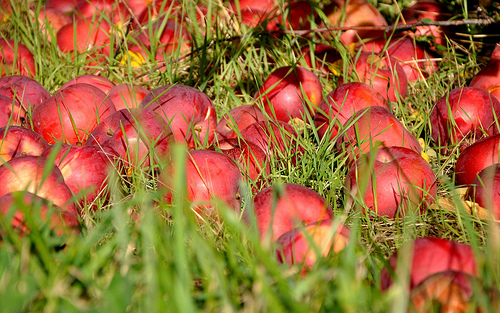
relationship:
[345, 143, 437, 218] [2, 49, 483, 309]
apple in field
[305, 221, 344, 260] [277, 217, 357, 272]
yellow spots on apple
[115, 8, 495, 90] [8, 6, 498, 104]
branch on apples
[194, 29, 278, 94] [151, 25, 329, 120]
shadow on grass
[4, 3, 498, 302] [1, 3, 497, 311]
apples strewn on ground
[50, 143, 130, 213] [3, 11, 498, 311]
apple in grass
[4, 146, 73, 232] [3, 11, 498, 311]
apple in grass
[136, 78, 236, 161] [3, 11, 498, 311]
apple in grass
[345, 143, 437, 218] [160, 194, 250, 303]
apple on floor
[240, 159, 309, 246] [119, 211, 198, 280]
apple on ground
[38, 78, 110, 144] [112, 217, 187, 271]
apple in grass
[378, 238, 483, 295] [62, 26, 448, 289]
apple in field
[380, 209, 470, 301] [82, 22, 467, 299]
apple in field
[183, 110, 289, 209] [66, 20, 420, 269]
apple in field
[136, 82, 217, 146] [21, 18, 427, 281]
apple in field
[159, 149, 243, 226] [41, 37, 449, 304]
apple in field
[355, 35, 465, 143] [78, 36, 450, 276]
apple in field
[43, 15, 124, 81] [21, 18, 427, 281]
apple in field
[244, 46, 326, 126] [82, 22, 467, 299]
apple in field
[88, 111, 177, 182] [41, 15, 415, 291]
apple in grass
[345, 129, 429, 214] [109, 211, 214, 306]
apple on grass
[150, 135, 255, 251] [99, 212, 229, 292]
apple on grass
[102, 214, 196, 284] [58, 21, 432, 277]
grass with apples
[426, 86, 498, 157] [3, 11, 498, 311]
apple laying in grass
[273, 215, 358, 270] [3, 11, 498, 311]
apple laying in grass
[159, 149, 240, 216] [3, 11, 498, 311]
apple laying in grass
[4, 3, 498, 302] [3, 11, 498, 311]
apples scattered in grass